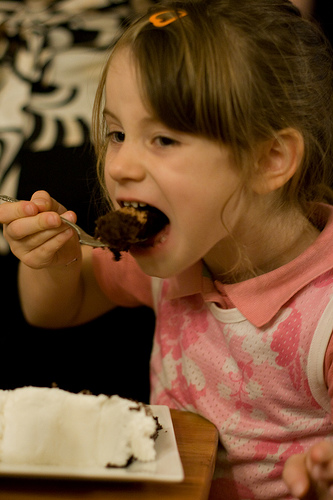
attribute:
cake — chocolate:
[95, 208, 144, 260]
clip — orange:
[147, 8, 190, 28]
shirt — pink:
[89, 197, 332, 498]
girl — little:
[7, 14, 314, 483]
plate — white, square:
[0, 402, 188, 486]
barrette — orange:
[146, 7, 194, 29]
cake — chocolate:
[93, 202, 151, 247]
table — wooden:
[2, 388, 217, 497]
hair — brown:
[89, 8, 326, 223]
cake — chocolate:
[92, 204, 168, 261]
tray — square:
[13, 379, 164, 492]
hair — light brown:
[91, 0, 332, 284]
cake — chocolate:
[4, 362, 141, 476]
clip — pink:
[146, 6, 187, 29]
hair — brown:
[0, 1, 331, 499]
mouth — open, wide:
[97, 191, 175, 245]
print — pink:
[155, 299, 224, 386]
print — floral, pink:
[157, 300, 222, 378]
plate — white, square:
[1, 381, 192, 487]